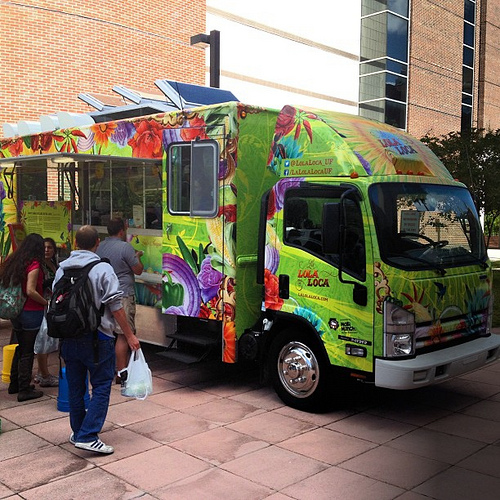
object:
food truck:
[1, 77, 499, 414]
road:
[0, 323, 500, 497]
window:
[461, 18, 478, 50]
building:
[0, 0, 500, 249]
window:
[360, 13, 410, 62]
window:
[357, 56, 410, 78]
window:
[358, 72, 410, 104]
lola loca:
[297, 268, 330, 287]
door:
[263, 179, 378, 372]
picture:
[161, 233, 228, 322]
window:
[83, 158, 163, 233]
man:
[44, 223, 141, 455]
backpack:
[44, 254, 108, 339]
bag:
[121, 346, 156, 403]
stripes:
[87, 439, 106, 449]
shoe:
[75, 439, 115, 458]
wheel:
[267, 322, 336, 414]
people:
[2, 211, 145, 461]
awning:
[2, 153, 166, 175]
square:
[1, 417, 51, 465]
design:
[94, 121, 121, 145]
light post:
[188, 27, 224, 90]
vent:
[75, 90, 128, 115]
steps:
[162, 328, 219, 369]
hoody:
[51, 250, 125, 341]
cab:
[264, 104, 499, 393]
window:
[164, 141, 217, 218]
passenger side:
[273, 177, 373, 373]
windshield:
[367, 178, 489, 273]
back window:
[18, 155, 78, 206]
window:
[284, 184, 366, 282]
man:
[97, 217, 145, 387]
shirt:
[96, 235, 141, 295]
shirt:
[15, 261, 46, 311]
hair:
[46, 237, 60, 265]